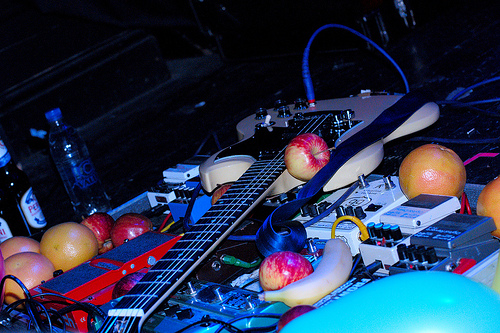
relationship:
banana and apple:
[257, 239, 356, 312] [255, 252, 315, 288]